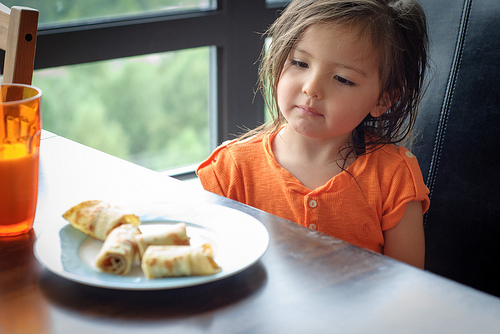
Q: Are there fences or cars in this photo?
A: No, there are no fences or cars.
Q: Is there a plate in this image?
A: Yes, there is a plate.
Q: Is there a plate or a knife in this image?
A: Yes, there is a plate.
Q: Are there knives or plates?
A: Yes, there is a plate.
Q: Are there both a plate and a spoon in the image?
A: No, there is a plate but no spoons.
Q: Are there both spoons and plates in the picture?
A: No, there is a plate but no spoons.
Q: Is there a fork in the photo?
A: No, there are no forks.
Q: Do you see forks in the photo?
A: No, there are no forks.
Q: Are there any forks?
A: No, there are no forks.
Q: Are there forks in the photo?
A: No, there are no forks.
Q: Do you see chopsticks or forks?
A: No, there are no forks or chopsticks.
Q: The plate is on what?
A: The plate is on the table.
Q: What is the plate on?
A: The plate is on the table.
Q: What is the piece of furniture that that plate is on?
A: The piece of furniture is a table.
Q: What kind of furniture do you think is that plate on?
A: The plate is on the table.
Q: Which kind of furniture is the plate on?
A: The plate is on the table.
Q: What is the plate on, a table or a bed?
A: The plate is on a table.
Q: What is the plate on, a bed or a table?
A: The plate is on a table.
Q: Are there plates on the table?
A: Yes, there is a plate on the table.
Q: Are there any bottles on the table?
A: No, there is a plate on the table.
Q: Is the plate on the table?
A: Yes, the plate is on the table.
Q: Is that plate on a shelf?
A: No, the plate is on the table.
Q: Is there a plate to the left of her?
A: Yes, there is a plate to the left of the girl.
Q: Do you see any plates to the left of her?
A: Yes, there is a plate to the left of the girl.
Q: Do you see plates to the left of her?
A: Yes, there is a plate to the left of the girl.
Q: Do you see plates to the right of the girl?
A: No, the plate is to the left of the girl.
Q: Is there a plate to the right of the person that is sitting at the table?
A: No, the plate is to the left of the girl.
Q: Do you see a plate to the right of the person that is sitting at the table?
A: No, the plate is to the left of the girl.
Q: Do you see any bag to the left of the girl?
A: No, there is a plate to the left of the girl.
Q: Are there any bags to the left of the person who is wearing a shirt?
A: No, there is a plate to the left of the girl.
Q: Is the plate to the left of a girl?
A: Yes, the plate is to the left of a girl.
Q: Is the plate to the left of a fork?
A: No, the plate is to the left of a girl.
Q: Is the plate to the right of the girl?
A: No, the plate is to the left of the girl.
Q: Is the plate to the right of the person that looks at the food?
A: No, the plate is to the left of the girl.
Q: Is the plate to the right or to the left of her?
A: The plate is to the left of the girl.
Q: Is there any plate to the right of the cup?
A: Yes, there is a plate to the right of the cup.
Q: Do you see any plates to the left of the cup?
A: No, the plate is to the right of the cup.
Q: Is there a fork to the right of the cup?
A: No, there is a plate to the right of the cup.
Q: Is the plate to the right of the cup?
A: Yes, the plate is to the right of the cup.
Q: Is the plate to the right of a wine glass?
A: No, the plate is to the right of the cup.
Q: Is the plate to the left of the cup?
A: No, the plate is to the right of the cup.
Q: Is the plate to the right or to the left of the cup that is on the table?
A: The plate is to the right of the cup.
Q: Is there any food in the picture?
A: Yes, there is food.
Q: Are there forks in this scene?
A: No, there are no forks.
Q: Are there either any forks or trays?
A: No, there are no forks or trays.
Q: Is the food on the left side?
A: Yes, the food is on the left of the image.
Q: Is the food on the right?
A: No, the food is on the left of the image.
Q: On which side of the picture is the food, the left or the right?
A: The food is on the left of the image.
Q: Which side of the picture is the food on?
A: The food is on the left of the image.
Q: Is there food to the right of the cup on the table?
A: Yes, there is food to the right of the cup.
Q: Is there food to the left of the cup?
A: No, the food is to the right of the cup.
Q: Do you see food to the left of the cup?
A: No, the food is to the right of the cup.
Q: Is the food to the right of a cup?
A: Yes, the food is to the right of a cup.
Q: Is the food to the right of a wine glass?
A: No, the food is to the right of a cup.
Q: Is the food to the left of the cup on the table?
A: No, the food is to the right of the cup.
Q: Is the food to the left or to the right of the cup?
A: The food is to the right of the cup.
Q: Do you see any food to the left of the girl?
A: Yes, there is food to the left of the girl.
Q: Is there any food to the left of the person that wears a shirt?
A: Yes, there is food to the left of the girl.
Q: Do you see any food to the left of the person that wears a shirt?
A: Yes, there is food to the left of the girl.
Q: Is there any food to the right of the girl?
A: No, the food is to the left of the girl.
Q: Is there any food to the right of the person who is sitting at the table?
A: No, the food is to the left of the girl.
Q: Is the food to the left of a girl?
A: Yes, the food is to the left of a girl.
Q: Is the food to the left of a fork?
A: No, the food is to the left of a girl.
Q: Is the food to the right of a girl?
A: No, the food is to the left of a girl.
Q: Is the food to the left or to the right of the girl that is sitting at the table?
A: The food is to the left of the girl.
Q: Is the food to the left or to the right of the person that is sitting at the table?
A: The food is to the left of the girl.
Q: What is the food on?
A: The food is on the table.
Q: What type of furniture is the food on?
A: The food is on the table.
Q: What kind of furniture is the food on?
A: The food is on the table.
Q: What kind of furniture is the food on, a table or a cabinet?
A: The food is on a table.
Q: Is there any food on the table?
A: Yes, there is food on the table.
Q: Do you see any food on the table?
A: Yes, there is food on the table.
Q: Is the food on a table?
A: Yes, the food is on a table.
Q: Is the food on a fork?
A: No, the food is on a table.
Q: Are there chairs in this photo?
A: Yes, there is a chair.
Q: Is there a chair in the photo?
A: Yes, there is a chair.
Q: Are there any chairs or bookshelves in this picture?
A: Yes, there is a chair.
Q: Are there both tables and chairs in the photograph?
A: Yes, there are both a chair and a table.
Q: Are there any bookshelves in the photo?
A: No, there are no bookshelves.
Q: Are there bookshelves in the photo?
A: No, there are no bookshelves.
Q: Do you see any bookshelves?
A: No, there are no bookshelves.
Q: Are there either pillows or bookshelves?
A: No, there are no bookshelves or pillows.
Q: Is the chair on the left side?
A: Yes, the chair is on the left of the image.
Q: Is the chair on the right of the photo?
A: No, the chair is on the left of the image.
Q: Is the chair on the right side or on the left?
A: The chair is on the left of the image.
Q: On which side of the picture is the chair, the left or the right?
A: The chair is on the left of the image.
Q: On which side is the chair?
A: The chair is on the left of the image.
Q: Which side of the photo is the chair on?
A: The chair is on the left of the image.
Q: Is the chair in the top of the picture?
A: Yes, the chair is in the top of the image.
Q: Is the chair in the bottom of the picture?
A: No, the chair is in the top of the image.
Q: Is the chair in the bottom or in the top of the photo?
A: The chair is in the top of the image.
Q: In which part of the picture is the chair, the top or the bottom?
A: The chair is in the top of the image.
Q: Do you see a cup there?
A: Yes, there is a cup.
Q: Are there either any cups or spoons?
A: Yes, there is a cup.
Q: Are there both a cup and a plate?
A: Yes, there are both a cup and a plate.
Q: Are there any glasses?
A: No, there are no glasses.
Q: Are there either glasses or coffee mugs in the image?
A: No, there are no glasses or coffee mugs.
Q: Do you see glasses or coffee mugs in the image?
A: No, there are no glasses or coffee mugs.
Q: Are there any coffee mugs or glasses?
A: No, there are no glasses or coffee mugs.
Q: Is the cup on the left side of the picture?
A: Yes, the cup is on the left of the image.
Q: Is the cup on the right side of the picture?
A: No, the cup is on the left of the image.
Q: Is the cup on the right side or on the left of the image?
A: The cup is on the left of the image.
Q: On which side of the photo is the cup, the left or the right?
A: The cup is on the left of the image.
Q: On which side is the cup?
A: The cup is on the left of the image.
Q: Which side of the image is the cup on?
A: The cup is on the left of the image.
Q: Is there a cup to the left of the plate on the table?
A: Yes, there is a cup to the left of the plate.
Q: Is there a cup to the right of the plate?
A: No, the cup is to the left of the plate.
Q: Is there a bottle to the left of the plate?
A: No, there is a cup to the left of the plate.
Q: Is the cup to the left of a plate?
A: Yes, the cup is to the left of a plate.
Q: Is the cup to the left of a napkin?
A: No, the cup is to the left of a plate.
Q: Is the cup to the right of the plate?
A: No, the cup is to the left of the plate.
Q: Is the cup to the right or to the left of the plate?
A: The cup is to the left of the plate.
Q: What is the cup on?
A: The cup is on the table.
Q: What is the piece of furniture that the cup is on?
A: The piece of furniture is a table.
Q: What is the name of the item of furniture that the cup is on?
A: The piece of furniture is a table.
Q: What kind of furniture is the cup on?
A: The cup is on the table.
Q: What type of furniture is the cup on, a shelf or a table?
A: The cup is on a table.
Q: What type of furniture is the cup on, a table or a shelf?
A: The cup is on a table.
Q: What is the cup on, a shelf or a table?
A: The cup is on a table.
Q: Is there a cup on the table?
A: Yes, there is a cup on the table.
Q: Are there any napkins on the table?
A: No, there is a cup on the table.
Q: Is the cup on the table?
A: Yes, the cup is on the table.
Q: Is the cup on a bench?
A: No, the cup is on the table.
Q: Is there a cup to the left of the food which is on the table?
A: Yes, there is a cup to the left of the food.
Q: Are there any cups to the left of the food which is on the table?
A: Yes, there is a cup to the left of the food.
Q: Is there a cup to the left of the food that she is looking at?
A: Yes, there is a cup to the left of the food.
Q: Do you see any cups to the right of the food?
A: No, the cup is to the left of the food.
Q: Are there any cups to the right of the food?
A: No, the cup is to the left of the food.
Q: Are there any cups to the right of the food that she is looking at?
A: No, the cup is to the left of the food.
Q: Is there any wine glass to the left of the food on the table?
A: No, there is a cup to the left of the food.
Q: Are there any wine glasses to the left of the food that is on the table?
A: No, there is a cup to the left of the food.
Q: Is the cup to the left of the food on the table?
A: Yes, the cup is to the left of the food.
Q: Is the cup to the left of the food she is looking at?
A: Yes, the cup is to the left of the food.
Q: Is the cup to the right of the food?
A: No, the cup is to the left of the food.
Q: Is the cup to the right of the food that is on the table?
A: No, the cup is to the left of the food.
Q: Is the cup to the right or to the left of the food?
A: The cup is to the left of the food.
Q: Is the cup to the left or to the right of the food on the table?
A: The cup is to the left of the food.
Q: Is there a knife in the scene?
A: No, there are no knives.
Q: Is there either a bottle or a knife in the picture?
A: No, there are no knives or bottles.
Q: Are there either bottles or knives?
A: No, there are no knives or bottles.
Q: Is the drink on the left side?
A: Yes, the drink is on the left of the image.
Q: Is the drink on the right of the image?
A: No, the drink is on the left of the image.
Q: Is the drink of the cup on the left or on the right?
A: The drink is on the left of the image.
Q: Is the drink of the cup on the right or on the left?
A: The drink is on the left of the image.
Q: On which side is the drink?
A: The drink is on the left of the image.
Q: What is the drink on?
A: The drink is on the table.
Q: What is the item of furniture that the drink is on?
A: The piece of furniture is a table.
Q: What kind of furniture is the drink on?
A: The drink is on the table.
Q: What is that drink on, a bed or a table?
A: The drink is on a table.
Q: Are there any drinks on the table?
A: Yes, there is a drink on the table.